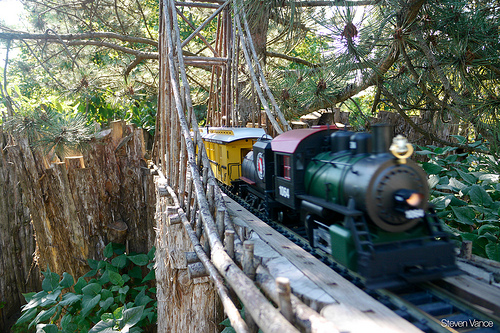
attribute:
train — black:
[183, 112, 461, 292]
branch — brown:
[21, 25, 206, 69]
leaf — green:
[128, 247, 155, 268]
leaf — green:
[55, 267, 75, 289]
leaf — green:
[471, 181, 492, 205]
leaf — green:
[115, 106, 130, 120]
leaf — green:
[57, 290, 84, 310]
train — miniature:
[218, 87, 483, 303]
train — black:
[199, 116, 466, 288]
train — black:
[191, 107, 468, 297]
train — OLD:
[181, 119, 483, 307]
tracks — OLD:
[395, 282, 465, 320]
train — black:
[105, 99, 468, 284]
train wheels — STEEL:
[273, 208, 315, 233]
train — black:
[196, 114, 446, 274]